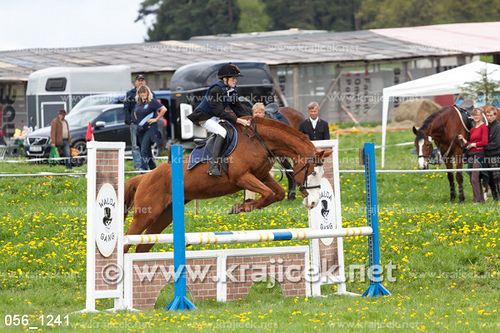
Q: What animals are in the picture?
A: Horses.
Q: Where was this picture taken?
A: Horse show.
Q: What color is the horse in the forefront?
A: Brown.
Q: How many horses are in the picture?
A: 3.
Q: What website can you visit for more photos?
A: Www.krajicek.net.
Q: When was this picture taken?
A: Last spring.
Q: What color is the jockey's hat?
A: Black.